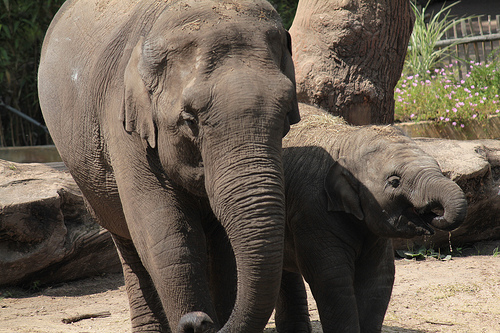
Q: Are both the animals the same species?
A: Yes, all the animals are elephants.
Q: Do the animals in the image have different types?
A: No, all the animals are elephants.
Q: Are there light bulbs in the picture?
A: No, there are no light bulbs.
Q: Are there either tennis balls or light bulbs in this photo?
A: No, there are no light bulbs or tennis balls.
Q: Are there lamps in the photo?
A: No, there are no lamps.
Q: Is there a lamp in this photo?
A: No, there are no lamps.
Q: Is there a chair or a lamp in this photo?
A: No, there are no lamps or chairs.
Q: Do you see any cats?
A: No, there are no cats.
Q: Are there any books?
A: No, there are no books.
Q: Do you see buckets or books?
A: No, there are no books or buckets.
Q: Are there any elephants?
A: Yes, there is an elephant.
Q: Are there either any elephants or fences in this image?
A: Yes, there is an elephant.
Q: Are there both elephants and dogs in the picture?
A: No, there is an elephant but no dogs.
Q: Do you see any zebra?
A: No, there are no zebras.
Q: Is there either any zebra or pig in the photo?
A: No, there are no zebras or pigs.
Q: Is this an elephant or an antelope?
A: This is an elephant.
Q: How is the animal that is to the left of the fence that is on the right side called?
A: The animal is an elephant.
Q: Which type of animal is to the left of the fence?
A: The animal is an elephant.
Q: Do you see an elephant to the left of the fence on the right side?
A: Yes, there is an elephant to the left of the fence.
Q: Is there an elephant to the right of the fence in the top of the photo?
A: No, the elephant is to the left of the fence.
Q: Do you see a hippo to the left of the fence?
A: No, there is an elephant to the left of the fence.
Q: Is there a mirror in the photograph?
A: No, there are no mirrors.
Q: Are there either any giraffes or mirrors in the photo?
A: No, there are no mirrors or giraffes.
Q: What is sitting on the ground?
A: The rock is sitting on the ground.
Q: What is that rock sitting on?
A: The rock is sitting on the ground.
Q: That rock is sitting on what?
A: The rock is sitting on the ground.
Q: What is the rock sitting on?
A: The rock is sitting on the ground.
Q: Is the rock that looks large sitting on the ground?
A: Yes, the rock is sitting on the ground.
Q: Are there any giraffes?
A: No, there are no giraffes.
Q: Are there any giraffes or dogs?
A: No, there are no giraffes or dogs.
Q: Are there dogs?
A: No, there are no dogs.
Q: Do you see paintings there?
A: No, there are no paintings.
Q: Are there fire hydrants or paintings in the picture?
A: No, there are no paintings or fire hydrants.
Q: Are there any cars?
A: No, there are no cars.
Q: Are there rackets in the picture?
A: No, there are no rackets.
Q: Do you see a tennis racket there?
A: No, there are no rackets.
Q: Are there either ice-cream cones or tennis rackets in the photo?
A: No, there are no tennis rackets or ice-cream cones.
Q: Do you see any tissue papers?
A: No, there are no tissue papers.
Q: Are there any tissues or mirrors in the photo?
A: No, there are no tissues or mirrors.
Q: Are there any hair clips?
A: No, there are no hair clips.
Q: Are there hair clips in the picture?
A: No, there are no hair clips.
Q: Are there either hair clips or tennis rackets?
A: No, there are no hair clips or tennis rackets.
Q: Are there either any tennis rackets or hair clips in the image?
A: No, there are no hair clips or tennis rackets.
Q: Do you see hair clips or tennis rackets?
A: No, there are no hair clips or tennis rackets.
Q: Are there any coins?
A: No, there are no coins.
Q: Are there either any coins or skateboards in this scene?
A: No, there are no coins or skateboards.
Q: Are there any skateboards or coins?
A: No, there are no coins or skateboards.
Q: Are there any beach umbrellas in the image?
A: No, there are no beach umbrellas.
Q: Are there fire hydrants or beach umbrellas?
A: No, there are no beach umbrellas or fire hydrants.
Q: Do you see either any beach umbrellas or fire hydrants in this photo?
A: No, there are no beach umbrellas or fire hydrants.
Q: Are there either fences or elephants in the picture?
A: Yes, there is an elephant.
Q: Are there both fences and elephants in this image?
A: Yes, there are both an elephant and a fence.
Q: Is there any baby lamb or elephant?
A: Yes, there is a baby elephant.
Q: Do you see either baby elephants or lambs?
A: Yes, there is a baby elephant.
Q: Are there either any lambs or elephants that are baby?
A: Yes, the elephant is a baby.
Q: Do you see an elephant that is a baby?
A: Yes, there is a baby elephant.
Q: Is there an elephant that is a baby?
A: Yes, there is an elephant that is a baby.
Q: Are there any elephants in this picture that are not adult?
A: Yes, there is an baby elephant.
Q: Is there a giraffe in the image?
A: No, there are no giraffes.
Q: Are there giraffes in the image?
A: No, there are no giraffes.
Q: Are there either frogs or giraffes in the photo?
A: No, there are no giraffes or frogs.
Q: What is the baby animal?
A: The animal is an elephant.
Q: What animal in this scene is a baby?
A: The animal is an elephant.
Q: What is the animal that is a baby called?
A: The animal is an elephant.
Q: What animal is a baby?
A: The animal is an elephant.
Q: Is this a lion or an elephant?
A: This is an elephant.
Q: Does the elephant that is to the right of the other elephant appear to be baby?
A: Yes, the elephant is a baby.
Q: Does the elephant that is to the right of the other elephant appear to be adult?
A: No, the elephant is a baby.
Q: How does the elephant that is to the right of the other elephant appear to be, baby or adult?
A: The elephant is a baby.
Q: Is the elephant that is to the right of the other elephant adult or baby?
A: The elephant is a baby.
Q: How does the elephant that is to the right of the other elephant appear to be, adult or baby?
A: The elephant is a baby.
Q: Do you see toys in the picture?
A: No, there are no toys.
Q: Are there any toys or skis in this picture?
A: No, there are no toys or skis.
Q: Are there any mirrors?
A: No, there are no mirrors.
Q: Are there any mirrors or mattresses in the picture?
A: No, there are no mirrors or mattresses.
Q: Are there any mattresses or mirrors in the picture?
A: No, there are no mirrors or mattresses.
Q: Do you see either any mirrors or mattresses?
A: No, there are no mirrors or mattresses.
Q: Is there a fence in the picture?
A: Yes, there is a fence.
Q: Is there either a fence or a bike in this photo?
A: Yes, there is a fence.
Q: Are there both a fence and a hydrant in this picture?
A: No, there is a fence but no fire hydrants.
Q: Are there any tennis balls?
A: No, there are no tennis balls.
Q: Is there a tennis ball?
A: No, there are no tennis balls.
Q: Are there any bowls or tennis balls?
A: No, there are no tennis balls or bowls.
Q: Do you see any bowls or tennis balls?
A: No, there are no tennis balls or bowls.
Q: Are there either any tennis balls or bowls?
A: No, there are no tennis balls or bowls.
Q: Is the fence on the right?
A: Yes, the fence is on the right of the image.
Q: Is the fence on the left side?
A: No, the fence is on the right of the image.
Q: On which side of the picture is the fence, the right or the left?
A: The fence is on the right of the image.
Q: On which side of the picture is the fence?
A: The fence is on the right of the image.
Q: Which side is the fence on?
A: The fence is on the right of the image.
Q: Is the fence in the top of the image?
A: Yes, the fence is in the top of the image.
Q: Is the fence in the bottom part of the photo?
A: No, the fence is in the top of the image.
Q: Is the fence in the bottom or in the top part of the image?
A: The fence is in the top of the image.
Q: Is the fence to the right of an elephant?
A: Yes, the fence is to the right of an elephant.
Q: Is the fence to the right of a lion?
A: No, the fence is to the right of an elephant.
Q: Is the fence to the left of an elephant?
A: No, the fence is to the right of an elephant.